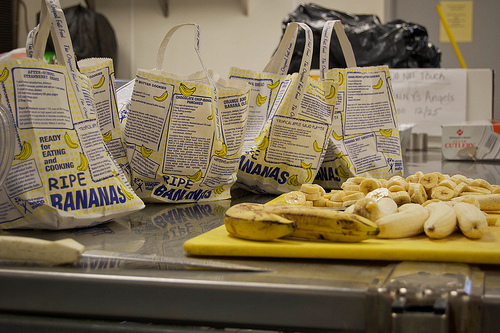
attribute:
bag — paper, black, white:
[5, 61, 145, 226]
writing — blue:
[48, 188, 126, 206]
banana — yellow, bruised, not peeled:
[225, 202, 294, 241]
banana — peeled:
[454, 204, 488, 239]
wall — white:
[18, 5, 383, 75]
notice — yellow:
[440, 0, 473, 45]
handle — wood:
[27, 1, 78, 68]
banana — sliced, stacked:
[414, 175, 460, 195]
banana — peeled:
[427, 201, 455, 241]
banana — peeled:
[381, 202, 428, 241]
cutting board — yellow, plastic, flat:
[184, 191, 499, 262]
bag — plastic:
[285, 5, 442, 71]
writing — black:
[398, 88, 457, 106]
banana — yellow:
[270, 207, 380, 240]